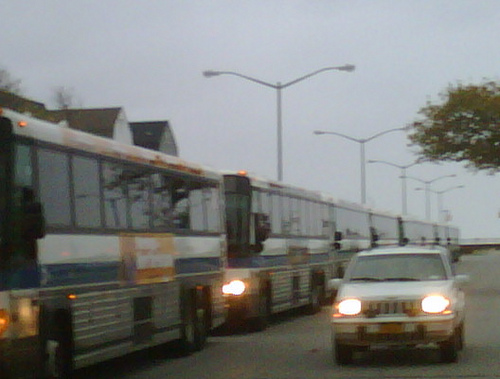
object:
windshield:
[345, 252, 446, 281]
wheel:
[332, 340, 348, 364]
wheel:
[440, 334, 459, 364]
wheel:
[453, 325, 461, 352]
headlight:
[226, 279, 247, 297]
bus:
[330, 201, 375, 302]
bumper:
[328, 314, 455, 328]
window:
[9, 141, 34, 191]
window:
[33, 144, 73, 227]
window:
[71, 150, 103, 230]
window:
[102, 155, 132, 231]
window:
[126, 160, 152, 230]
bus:
[0, 105, 233, 378]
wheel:
[186, 291, 214, 351]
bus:
[367, 210, 401, 248]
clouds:
[0, 0, 499, 241]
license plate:
[375, 321, 406, 336]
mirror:
[322, 277, 344, 293]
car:
[325, 243, 469, 366]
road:
[106, 248, 499, 379]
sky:
[0, 0, 499, 238]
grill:
[367, 299, 414, 317]